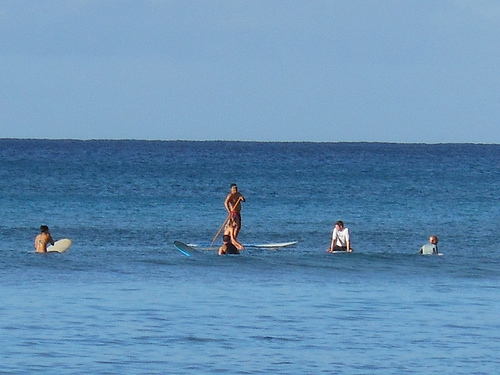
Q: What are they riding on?
A: Surfboards.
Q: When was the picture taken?
A: In the daytime.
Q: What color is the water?
A: Blue.